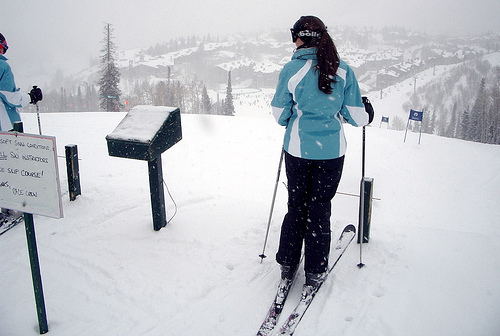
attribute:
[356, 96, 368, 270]
ski pole — grey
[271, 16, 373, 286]
girl — standing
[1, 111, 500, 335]
snow — white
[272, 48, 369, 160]
jacket — blue, white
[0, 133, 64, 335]
sign — white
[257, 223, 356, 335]
skis — black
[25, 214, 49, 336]
pole — black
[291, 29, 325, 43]
goggles — black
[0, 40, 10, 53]
goggles — red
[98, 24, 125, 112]
tree — large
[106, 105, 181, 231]
box — black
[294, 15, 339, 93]
hair — long, dark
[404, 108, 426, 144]
ski marker — blue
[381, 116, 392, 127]
ski marker — blue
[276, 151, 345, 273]
pants — black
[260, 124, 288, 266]
ski pole — grey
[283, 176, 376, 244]
gate — black